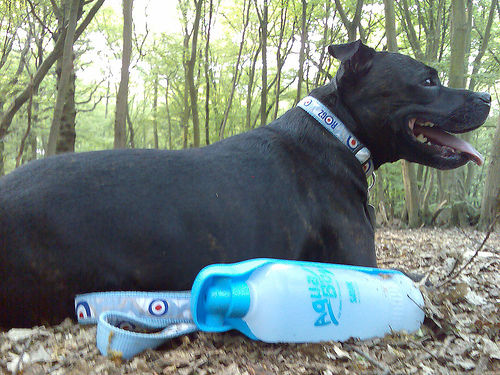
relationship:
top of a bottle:
[200, 279, 252, 318] [181, 243, 461, 357]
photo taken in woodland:
[7, 10, 497, 371] [5, 5, 476, 109]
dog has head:
[0, 39, 493, 331] [324, 27, 479, 167]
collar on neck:
[296, 95, 378, 222] [276, 84, 369, 185]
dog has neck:
[0, 39, 493, 331] [276, 84, 369, 185]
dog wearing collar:
[0, 39, 493, 331] [296, 95, 375, 178]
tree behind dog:
[116, 0, 130, 149] [0, 39, 493, 331]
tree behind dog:
[49, 2, 84, 154] [0, 39, 493, 331]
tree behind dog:
[186, 7, 205, 147] [0, 39, 493, 331]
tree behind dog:
[260, 2, 270, 124] [0, 39, 493, 331]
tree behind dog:
[294, 0, 309, 105] [0, 39, 493, 331]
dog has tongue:
[0, 39, 493, 331] [410, 117, 485, 165]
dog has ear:
[127, 17, 494, 271] [327, 38, 377, 78]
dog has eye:
[0, 39, 493, 331] [416, 74, 437, 88]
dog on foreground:
[0, 39, 493, 331] [12, 177, 495, 293]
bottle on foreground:
[193, 256, 425, 348] [6, 234, 498, 308]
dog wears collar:
[0, 39, 493, 331] [292, 88, 379, 189]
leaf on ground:
[455, 302, 477, 314] [0, 225, 492, 373]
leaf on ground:
[434, 264, 454, 288] [0, 225, 492, 373]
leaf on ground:
[480, 270, 487, 286] [0, 225, 492, 373]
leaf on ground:
[358, 342, 388, 369] [0, 225, 492, 373]